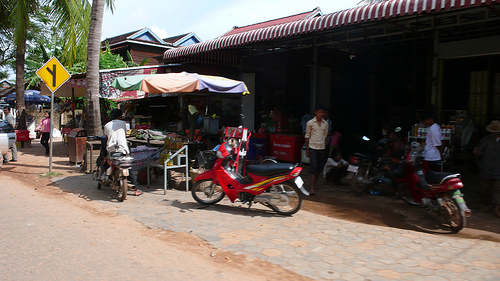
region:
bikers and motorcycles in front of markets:
[11, 12, 471, 244]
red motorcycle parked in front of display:
[160, 100, 312, 222]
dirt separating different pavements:
[27, 145, 272, 275]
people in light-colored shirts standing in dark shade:
[300, 90, 457, 181]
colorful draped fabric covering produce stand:
[110, 65, 250, 112]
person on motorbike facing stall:
[65, 100, 145, 200]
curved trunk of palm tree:
[75, 11, 115, 136]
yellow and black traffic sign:
[15, 50, 80, 195]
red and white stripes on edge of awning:
[160, 0, 470, 65]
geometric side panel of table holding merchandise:
[140, 133, 191, 199]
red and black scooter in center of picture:
[187, 134, 310, 213]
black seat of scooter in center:
[246, 161, 298, 172]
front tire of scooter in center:
[191, 175, 226, 207]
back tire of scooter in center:
[268, 178, 302, 213]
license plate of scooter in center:
[295, 173, 302, 188]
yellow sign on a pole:
[36, 54, 71, 176]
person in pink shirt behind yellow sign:
[37, 111, 52, 156]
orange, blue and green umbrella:
[111, 66, 252, 94]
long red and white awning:
[160, 1, 498, 65]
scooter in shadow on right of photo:
[397, 156, 470, 234]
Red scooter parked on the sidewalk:
[182, 128, 312, 225]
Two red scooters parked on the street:
[184, 118, 476, 235]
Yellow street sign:
[27, 51, 77, 181]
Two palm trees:
[2, 0, 112, 152]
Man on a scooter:
[95, 98, 136, 213]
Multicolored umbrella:
[110, 65, 255, 105]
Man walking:
[300, 96, 342, 211]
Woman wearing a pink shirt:
[30, 100, 61, 156]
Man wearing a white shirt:
[410, 106, 450, 176]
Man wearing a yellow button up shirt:
[300, 105, 333, 161]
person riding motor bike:
[93, 96, 142, 214]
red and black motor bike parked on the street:
[179, 125, 321, 228]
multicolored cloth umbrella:
[105, 51, 260, 111]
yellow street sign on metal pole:
[26, 41, 80, 188]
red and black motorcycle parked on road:
[377, 136, 478, 246]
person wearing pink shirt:
[27, 103, 61, 166]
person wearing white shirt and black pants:
[292, 93, 341, 199]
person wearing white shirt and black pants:
[401, 108, 465, 199]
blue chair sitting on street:
[137, 124, 197, 208]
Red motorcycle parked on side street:
[183, 119, 317, 221]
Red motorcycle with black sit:
[390, 150, 475, 236]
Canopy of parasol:
[102, 60, 252, 102]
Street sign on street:
[27, 52, 78, 187]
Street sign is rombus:
[27, 50, 79, 97]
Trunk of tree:
[70, 0, 111, 146]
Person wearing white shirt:
[412, 107, 448, 187]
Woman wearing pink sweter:
[30, 108, 58, 159]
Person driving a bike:
[92, 100, 142, 210]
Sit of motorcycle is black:
[243, 157, 302, 175]